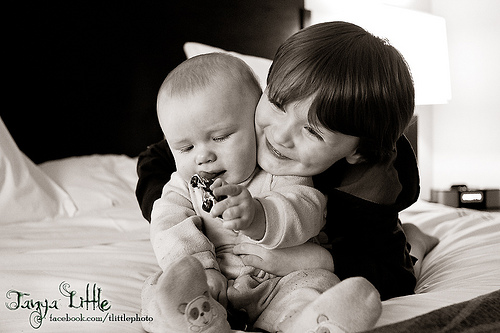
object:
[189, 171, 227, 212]
car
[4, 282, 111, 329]
signature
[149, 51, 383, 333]
boy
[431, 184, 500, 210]
clock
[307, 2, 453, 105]
lamp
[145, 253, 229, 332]
feet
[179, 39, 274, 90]
pillow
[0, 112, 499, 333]
bed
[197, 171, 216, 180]
tongue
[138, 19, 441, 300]
child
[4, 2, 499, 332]
photo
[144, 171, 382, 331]
pajamas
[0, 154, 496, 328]
sheets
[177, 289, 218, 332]
teddy bear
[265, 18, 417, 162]
hair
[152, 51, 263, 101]
hair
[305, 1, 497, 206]
wall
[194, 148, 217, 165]
nose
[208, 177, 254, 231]
hand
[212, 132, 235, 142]
eye